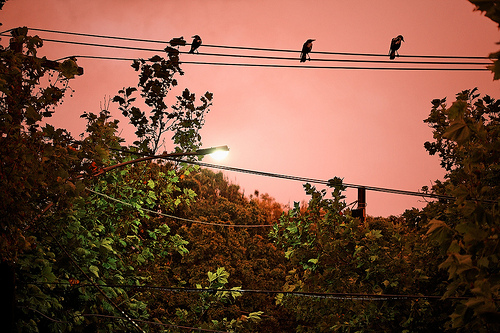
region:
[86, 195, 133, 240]
these are leaves on a branch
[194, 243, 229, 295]
these are leaves on a branch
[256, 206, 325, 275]
these are leaves on a branch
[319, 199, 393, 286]
these are leaves on a branch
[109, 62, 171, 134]
these are leaves on a branch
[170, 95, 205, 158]
these are leaves on a branch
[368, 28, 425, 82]
this is a bird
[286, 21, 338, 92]
this is a bird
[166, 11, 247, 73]
this is a bird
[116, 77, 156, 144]
these are leaves on a branch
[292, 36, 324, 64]
Small bird sitting on wire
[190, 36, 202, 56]
Small bird sitting on wire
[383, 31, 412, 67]
Small bird sitting on wire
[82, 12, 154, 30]
Part of beautiful sky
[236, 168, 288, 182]
Part of electrical wire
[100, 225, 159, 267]
Part of green trees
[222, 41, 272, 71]
Part of electrical wires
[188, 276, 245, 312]
Part of green tree foilage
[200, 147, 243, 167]
Setting sun in sky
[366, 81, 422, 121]
Beautiful color in sky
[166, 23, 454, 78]
birds on a wire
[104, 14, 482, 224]
the sky is pink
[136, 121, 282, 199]
the street light is on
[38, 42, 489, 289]
the season is fall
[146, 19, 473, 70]
there are four birds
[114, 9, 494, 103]
there are three wires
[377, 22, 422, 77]
the bird is black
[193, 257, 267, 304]
the light shines through the leaves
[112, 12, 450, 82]
two birds on the middle wire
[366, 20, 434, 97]
the bird on the top wire